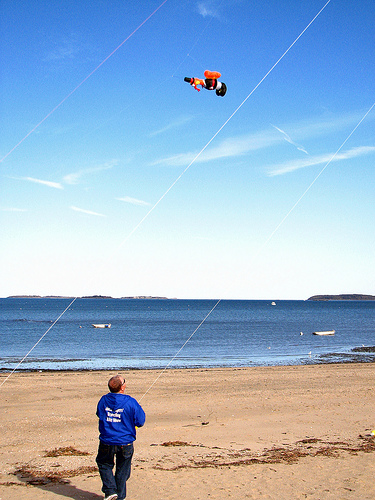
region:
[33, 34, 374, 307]
blue sky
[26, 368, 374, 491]
tan sand on the beach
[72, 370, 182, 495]
a man wearing sunglasses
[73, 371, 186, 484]
a man wearing a blue sweatshirt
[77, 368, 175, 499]
a man wearing blue jeans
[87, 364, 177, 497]
a man wearing sneakers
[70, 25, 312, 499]
a man flying a kite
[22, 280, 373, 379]
blue water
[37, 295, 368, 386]
boats on the water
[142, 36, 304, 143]
a kite in the sky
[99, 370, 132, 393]
The person has hair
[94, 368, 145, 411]
The person has brown hair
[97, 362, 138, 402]
The person has short hair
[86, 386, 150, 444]
The person is wearing a coat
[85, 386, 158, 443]
The person is wearing a blue coat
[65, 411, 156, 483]
The person is wearing jeans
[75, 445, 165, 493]
The person is wearing blue jeans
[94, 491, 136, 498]
The person is wearing shoes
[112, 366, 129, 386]
The person is wearing glasses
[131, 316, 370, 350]
The picture has water in it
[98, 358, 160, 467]
man at the beach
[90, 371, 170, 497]
man at the beach holding a kite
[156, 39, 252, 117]
a kite flying in th sky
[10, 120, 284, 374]
strings of the frisbee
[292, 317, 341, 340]
a boat in the water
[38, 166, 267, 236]
water in the clouds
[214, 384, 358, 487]
sand on the beach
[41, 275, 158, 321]
mountains in the background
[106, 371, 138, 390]
kite man's face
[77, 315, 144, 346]
small boat sitting in the water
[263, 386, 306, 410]
section of a sandy beach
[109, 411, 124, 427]
back of a man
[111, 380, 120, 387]
head of a man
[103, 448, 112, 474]
left leg of a man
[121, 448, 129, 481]
right leg of a man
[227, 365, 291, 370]
section of an ocean shore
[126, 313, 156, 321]
section of the sea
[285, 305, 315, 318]
part of the ocean water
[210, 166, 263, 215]
part of the sky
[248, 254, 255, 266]
string of a kite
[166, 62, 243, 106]
A colorful kite in the shape of a pilgrim high in the air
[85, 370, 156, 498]
a man in a blue hoodie and sunglasses flying a kite at the beach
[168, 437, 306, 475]
large piles of seaweed on the beach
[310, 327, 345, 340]
a small white boat floating in the water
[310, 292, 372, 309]
a low mountain across the water in the distance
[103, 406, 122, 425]
white writing on the back of the man's blue shirt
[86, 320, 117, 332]
a small white boat floating in the water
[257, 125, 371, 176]
a few white streaky clouds in the blue sky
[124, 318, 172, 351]
a rather calm blue body of water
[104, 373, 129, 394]
the head of the man flying the kite